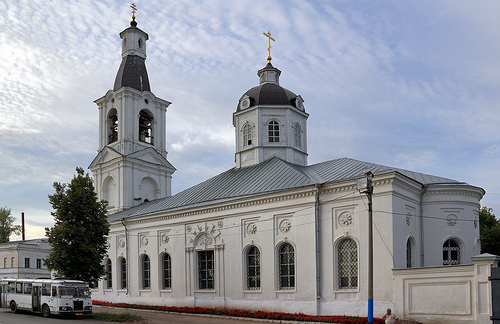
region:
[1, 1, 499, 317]
photo was taken oudoors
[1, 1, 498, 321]
the scene is during daytime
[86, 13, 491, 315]
a white church is shown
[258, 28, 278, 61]
a golden cross atop the church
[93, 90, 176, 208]
the bell tower is painted white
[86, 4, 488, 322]
the church is painted white with a grey roof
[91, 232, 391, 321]
many windows on the side of the church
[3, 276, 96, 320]
a white bus is passing by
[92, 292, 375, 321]
red flowers along side of church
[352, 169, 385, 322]
a light pole is in front of church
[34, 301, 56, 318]
Front tire on the bus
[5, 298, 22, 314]
Rear tire on the bus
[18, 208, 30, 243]
Pipe on top of the small building on the left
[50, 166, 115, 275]
Large tree in front of the building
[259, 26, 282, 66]
Cross on top of the lower steeple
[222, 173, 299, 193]
Roof of the church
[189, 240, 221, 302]
Square windoe in the middle of the church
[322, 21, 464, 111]
Blue sky behind the church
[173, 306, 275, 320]
Red flowers in front of the church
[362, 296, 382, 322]
Blue base of the pole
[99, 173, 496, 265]
the walls i white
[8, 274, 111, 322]
the bus is white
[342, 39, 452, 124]
the sky is blue and white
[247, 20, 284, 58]
the cross is gold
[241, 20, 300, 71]
the cross is on top of the roof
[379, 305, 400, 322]
man beside the pole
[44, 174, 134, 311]
the tree is green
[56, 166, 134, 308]
the tree is in front of the church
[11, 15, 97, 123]
the sky is cloudy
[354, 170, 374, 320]
the pole is tall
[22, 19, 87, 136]
Some clouds are in sky.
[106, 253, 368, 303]
The windows are in the wall of the building.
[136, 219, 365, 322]
the walls are white in color.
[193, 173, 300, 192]
the roof is grey in color.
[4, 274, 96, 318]
The bus is white in color.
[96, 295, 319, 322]
Red color bushes are lined down to the sides of the wall.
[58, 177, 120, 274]
Leaves are green in color.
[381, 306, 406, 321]
One man is standing.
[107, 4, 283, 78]
Two tower has cross symbol in the top.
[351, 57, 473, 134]
Sky is blue in color.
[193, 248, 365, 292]
The church has a lot of windows.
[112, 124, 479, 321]
The church is white.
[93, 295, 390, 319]
The church is trimmed with flowers at the bottom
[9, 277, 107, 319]
A bus is driving down the street.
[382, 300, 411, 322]
A man is standing by the church wall.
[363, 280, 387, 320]
The bottom of the pole is blue.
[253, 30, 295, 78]
The church has a gold cross on the top.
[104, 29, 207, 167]
The temple is very high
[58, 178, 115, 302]
The green tree is next to the church.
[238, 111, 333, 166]
The temple has windows